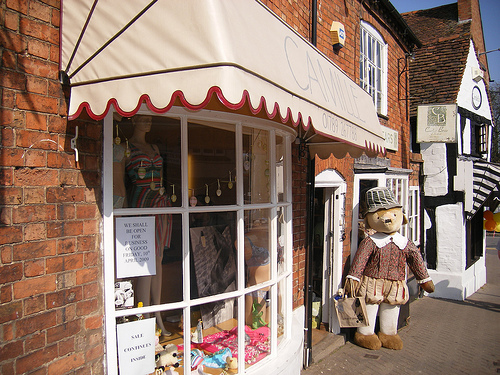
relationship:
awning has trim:
[53, 0, 393, 161] [66, 84, 389, 160]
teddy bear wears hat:
[331, 181, 437, 356] [359, 182, 404, 218]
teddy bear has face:
[331, 181, 437, 356] [364, 206, 405, 236]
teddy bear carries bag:
[331, 181, 437, 356] [331, 275, 371, 330]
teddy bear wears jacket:
[331, 181, 437, 356] [341, 228, 432, 283]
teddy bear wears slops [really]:
[331, 181, 437, 356] [347, 271, 413, 308]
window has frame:
[101, 97, 309, 373] [102, 99, 290, 373]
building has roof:
[402, 1, 497, 304] [403, 33, 497, 125]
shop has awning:
[404, 30, 500, 305] [458, 157, 499, 221]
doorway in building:
[310, 165, 348, 342] [1, 0, 412, 374]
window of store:
[101, 97, 309, 373] [58, 0, 390, 374]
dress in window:
[122, 136, 175, 254] [101, 97, 309, 373]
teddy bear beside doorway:
[331, 181, 437, 356] [310, 165, 348, 342]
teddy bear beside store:
[331, 181, 437, 356] [58, 0, 390, 374]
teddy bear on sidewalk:
[331, 181, 437, 356] [300, 254, 499, 375]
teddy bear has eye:
[331, 181, 437, 356] [392, 210, 399, 218]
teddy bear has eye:
[331, 181, 437, 356] [376, 215, 383, 222]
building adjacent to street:
[402, 1, 497, 304] [483, 228, 500, 258]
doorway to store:
[310, 165, 348, 342] [58, 0, 390, 374]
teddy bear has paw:
[331, 181, 437, 356] [418, 278, 436, 297]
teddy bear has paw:
[331, 181, 437, 356] [339, 277, 361, 298]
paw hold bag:
[339, 277, 361, 298] [331, 275, 371, 330]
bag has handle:
[331, 275, 371, 330] [340, 273, 357, 300]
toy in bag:
[336, 287, 348, 300] [331, 275, 371, 330]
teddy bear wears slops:
[331, 181, 437, 356] [355, 273, 412, 309]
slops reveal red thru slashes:
[355, 273, 412, 309] [367, 277, 408, 305]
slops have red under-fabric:
[355, 273, 412, 309] [364, 277, 407, 306]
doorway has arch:
[310, 165, 348, 342] [316, 168, 346, 186]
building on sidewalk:
[1, 0, 412, 374] [300, 254, 499, 375]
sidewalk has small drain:
[300, 254, 499, 375] [362, 350, 382, 363]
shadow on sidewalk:
[432, 294, 500, 314] [300, 254, 499, 375]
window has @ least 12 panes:
[101, 97, 309, 373] [111, 111, 288, 374]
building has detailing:
[402, 1, 497, 304] [407, 102, 484, 274]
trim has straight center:
[66, 84, 389, 160] [313, 123, 366, 151]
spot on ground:
[338, 363, 348, 371] [300, 231, 498, 374]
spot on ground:
[342, 357, 350, 364] [300, 231, 498, 374]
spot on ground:
[331, 361, 338, 370] [300, 231, 498, 374]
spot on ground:
[316, 366, 323, 373] [300, 231, 498, 374]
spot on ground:
[415, 366, 427, 373] [300, 231, 498, 374]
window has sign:
[101, 97, 309, 373] [113, 315, 163, 374]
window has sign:
[101, 97, 309, 373] [114, 214, 159, 281]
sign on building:
[414, 103, 459, 147] [402, 1, 497, 304]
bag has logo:
[331, 275, 371, 330] [338, 298, 366, 327]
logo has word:
[338, 298, 366, 327] [339, 310, 359, 325]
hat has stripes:
[359, 182, 404, 218] [365, 186, 398, 210]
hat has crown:
[359, 182, 404, 218] [364, 183, 393, 194]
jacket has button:
[341, 228, 432, 283] [388, 236, 395, 242]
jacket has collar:
[341, 228, 432, 283] [362, 229, 410, 250]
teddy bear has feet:
[331, 181, 437, 356] [352, 331, 408, 354]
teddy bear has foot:
[331, 181, 437, 356] [375, 329, 405, 353]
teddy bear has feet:
[331, 181, 437, 356] [352, 331, 383, 351]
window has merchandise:
[101, 97, 309, 373] [102, 99, 290, 373]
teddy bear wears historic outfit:
[331, 181, 437, 356] [355, 275, 412, 334]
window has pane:
[101, 97, 309, 373] [186, 210, 241, 299]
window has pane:
[101, 97, 309, 373] [238, 208, 272, 289]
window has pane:
[101, 97, 309, 373] [244, 286, 271, 362]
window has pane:
[101, 97, 309, 373] [276, 282, 290, 346]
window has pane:
[101, 97, 309, 373] [185, 118, 239, 208]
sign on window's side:
[113, 315, 163, 374] [108, 105, 190, 374]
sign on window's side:
[114, 214, 159, 281] [108, 105, 190, 374]